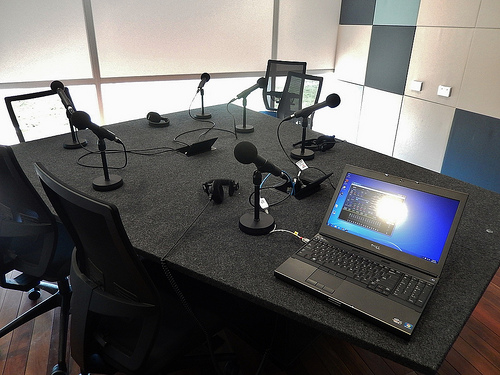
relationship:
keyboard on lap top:
[293, 235, 435, 313] [295, 235, 447, 310]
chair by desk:
[31, 161, 252, 375] [3, 103, 496, 372]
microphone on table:
[234, 141, 289, 182] [8, 90, 492, 372]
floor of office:
[2, 282, 68, 373] [1, 2, 494, 374]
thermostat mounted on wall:
[407, 78, 423, 94] [325, 12, 455, 45]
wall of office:
[0, 0, 335, 137] [1, 2, 494, 374]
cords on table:
[108, 138, 185, 161] [32, 60, 282, 295]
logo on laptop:
[391, 317, 413, 331] [273, 163, 468, 338]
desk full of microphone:
[128, 172, 188, 224] [234, 141, 289, 182]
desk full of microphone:
[128, 172, 188, 224] [284, 93, 341, 160]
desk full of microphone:
[128, 172, 188, 224] [232, 77, 269, 132]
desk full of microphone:
[128, 172, 188, 224] [71, 112, 126, 193]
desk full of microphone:
[128, 172, 188, 224] [194, 73, 213, 120]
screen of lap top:
[331, 165, 439, 255] [317, 150, 427, 332]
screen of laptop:
[326, 172, 459, 264] [273, 163, 468, 338]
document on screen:
[337, 180, 409, 237] [326, 172, 459, 264]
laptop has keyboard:
[273, 163, 468, 338] [293, 235, 435, 313]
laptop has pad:
[273, 163, 468, 338] [305, 264, 344, 293]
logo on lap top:
[385, 314, 415, 334] [293, 146, 450, 319]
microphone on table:
[230, 140, 297, 233] [8, 90, 492, 372]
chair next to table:
[30, 161, 216, 373] [8, 90, 492, 372]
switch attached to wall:
[407, 70, 474, 121] [308, 0, 498, 190]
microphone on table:
[33, 66, 97, 152] [8, 90, 492, 372]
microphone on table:
[185, 68, 215, 121] [8, 90, 492, 372]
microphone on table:
[227, 74, 269, 136] [35, 49, 494, 356]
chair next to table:
[27, 156, 205, 370] [8, 90, 492, 372]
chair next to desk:
[278, 75, 311, 135] [9, 103, 500, 375]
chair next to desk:
[259, 53, 281, 95] [9, 103, 500, 375]